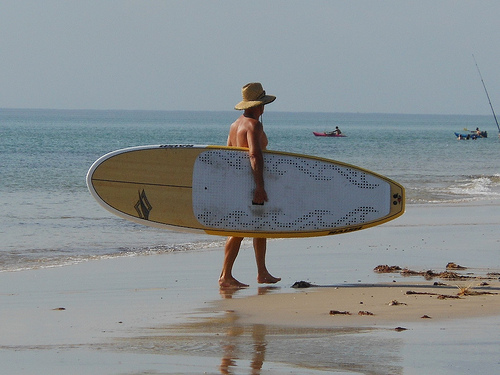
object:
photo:
[0, 2, 500, 375]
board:
[84, 139, 406, 244]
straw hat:
[232, 80, 278, 111]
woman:
[328, 126, 343, 136]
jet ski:
[311, 131, 346, 138]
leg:
[251, 236, 271, 274]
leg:
[222, 233, 243, 277]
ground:
[386, 165, 404, 198]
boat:
[452, 125, 488, 140]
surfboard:
[85, 134, 407, 238]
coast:
[0, 200, 499, 373]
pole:
[466, 54, 497, 134]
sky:
[0, 0, 500, 110]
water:
[1, 105, 500, 270]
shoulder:
[242, 120, 263, 138]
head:
[233, 80, 278, 115]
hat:
[233, 80, 276, 112]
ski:
[311, 127, 346, 137]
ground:
[0, 239, 497, 374]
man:
[216, 82, 280, 291]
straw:
[253, 90, 261, 92]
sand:
[0, 226, 500, 375]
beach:
[0, 212, 499, 373]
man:
[329, 125, 344, 137]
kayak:
[309, 129, 340, 139]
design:
[266, 198, 387, 238]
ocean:
[0, 141, 500, 271]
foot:
[216, 267, 250, 292]